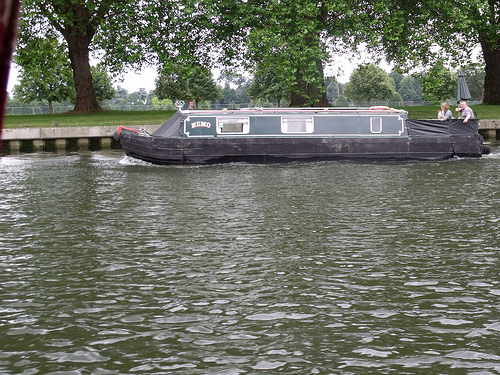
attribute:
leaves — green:
[253, 20, 279, 56]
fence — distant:
[2, 94, 478, 115]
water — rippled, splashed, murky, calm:
[0, 151, 498, 371]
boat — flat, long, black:
[107, 104, 487, 168]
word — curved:
[189, 119, 213, 128]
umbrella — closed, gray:
[451, 65, 477, 103]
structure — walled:
[4, 129, 132, 148]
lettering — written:
[190, 120, 211, 132]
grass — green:
[6, 114, 169, 128]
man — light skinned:
[453, 96, 476, 123]